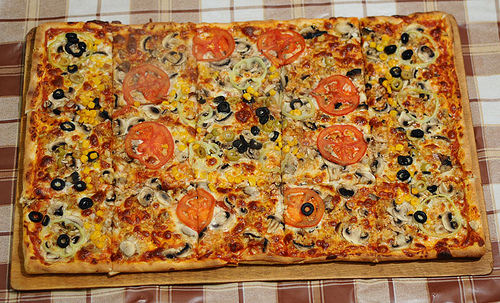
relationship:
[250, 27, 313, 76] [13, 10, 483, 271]
tomato slice on pizza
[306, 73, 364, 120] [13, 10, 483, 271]
tomato slice on pizza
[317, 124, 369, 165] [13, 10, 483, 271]
tomato on pizza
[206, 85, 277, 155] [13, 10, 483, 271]
olives on pizza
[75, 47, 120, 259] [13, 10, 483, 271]
corn on pizza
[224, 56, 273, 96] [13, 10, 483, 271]
onion ring on pizza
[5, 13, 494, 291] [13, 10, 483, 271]
board under pizza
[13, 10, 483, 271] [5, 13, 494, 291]
pizza on board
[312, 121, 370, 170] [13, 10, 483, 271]
tomato on pizza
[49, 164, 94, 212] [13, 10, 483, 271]
olives on pizza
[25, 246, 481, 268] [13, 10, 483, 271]
crust of pizza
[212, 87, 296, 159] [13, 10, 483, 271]
middle of pizza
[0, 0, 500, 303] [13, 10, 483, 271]
table cloth under pizza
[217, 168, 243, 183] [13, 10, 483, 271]
topping on pizza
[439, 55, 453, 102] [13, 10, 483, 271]
sauce on pizza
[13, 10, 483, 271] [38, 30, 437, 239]
pizza with toppings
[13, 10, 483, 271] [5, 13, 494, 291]
pizza in a board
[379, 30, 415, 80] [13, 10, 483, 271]
olives on pizza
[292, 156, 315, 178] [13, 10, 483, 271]
cheese on pizza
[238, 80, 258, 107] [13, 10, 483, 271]
corn on pizza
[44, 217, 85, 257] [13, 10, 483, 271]
onions on pizza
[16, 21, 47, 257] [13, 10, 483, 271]
crust of pizza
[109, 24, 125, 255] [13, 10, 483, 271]
slices cut into pizza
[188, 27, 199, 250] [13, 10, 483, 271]
slices cut into pizza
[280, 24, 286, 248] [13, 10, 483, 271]
slices cut into pizza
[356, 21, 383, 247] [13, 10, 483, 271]
slices cut into pizza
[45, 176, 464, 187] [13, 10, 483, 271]
slices cut into pizza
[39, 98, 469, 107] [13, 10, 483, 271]
slices cut into pizza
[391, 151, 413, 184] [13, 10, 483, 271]
olives on pizza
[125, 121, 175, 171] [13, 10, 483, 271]
tomato on pizza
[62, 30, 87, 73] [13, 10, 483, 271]
olives on pizza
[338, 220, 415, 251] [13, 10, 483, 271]
mushrooms on pizza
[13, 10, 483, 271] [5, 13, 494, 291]
pizza on a board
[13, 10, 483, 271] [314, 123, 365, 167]
pizza with tomato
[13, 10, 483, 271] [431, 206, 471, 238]
pizza with mushroom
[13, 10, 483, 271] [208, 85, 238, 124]
pizza with black olive